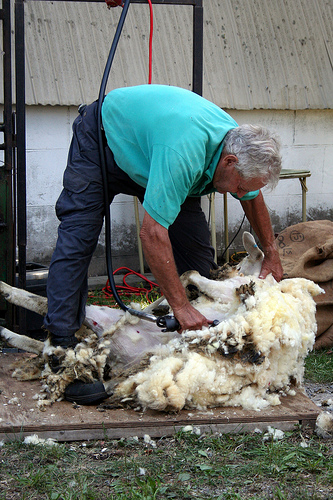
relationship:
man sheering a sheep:
[44, 82, 285, 371] [0, 230, 326, 410]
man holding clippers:
[44, 82, 285, 371] [155, 316, 219, 332]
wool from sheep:
[122, 273, 324, 412] [0, 230, 326, 410]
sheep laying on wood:
[0, 230, 326, 410] [0, 353, 324, 445]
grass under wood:
[0, 286, 332, 499] [0, 353, 324, 445]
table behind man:
[211, 168, 311, 266] [44, 82, 285, 371]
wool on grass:
[26, 413, 331, 456] [0, 286, 332, 499]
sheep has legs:
[0, 230, 326, 410] [1, 281, 104, 372]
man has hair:
[44, 82, 285, 371] [226, 124, 282, 190]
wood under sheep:
[0, 353, 324, 445] [0, 230, 326, 410]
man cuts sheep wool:
[44, 82, 285, 371] [122, 273, 324, 412]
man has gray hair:
[44, 82, 285, 371] [226, 124, 282, 190]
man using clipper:
[44, 82, 285, 371] [155, 316, 219, 332]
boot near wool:
[49, 336, 109, 405] [122, 273, 324, 412]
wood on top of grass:
[0, 353, 324, 445] [0, 286, 332, 499]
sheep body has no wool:
[0, 230, 326, 410] [122, 273, 324, 412]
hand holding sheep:
[261, 251, 284, 282] [0, 230, 326, 410]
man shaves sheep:
[44, 82, 285, 371] [0, 230, 326, 410]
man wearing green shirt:
[44, 82, 285, 371] [104, 84, 260, 229]